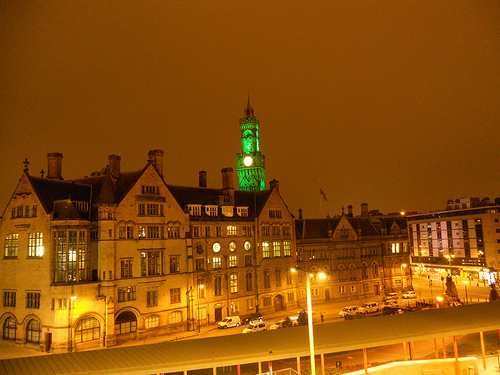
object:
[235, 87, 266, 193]
clock tower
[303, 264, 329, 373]
street light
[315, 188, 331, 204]
flag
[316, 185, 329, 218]
pole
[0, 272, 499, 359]
street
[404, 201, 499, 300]
building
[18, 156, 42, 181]
sculptures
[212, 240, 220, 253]
lights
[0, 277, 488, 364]
walkway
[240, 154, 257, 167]
clock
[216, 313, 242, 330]
van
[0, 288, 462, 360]
roadway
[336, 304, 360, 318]
vehicles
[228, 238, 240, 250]
windows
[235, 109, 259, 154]
steeple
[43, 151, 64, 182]
chimneys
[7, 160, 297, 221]
roof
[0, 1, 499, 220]
sky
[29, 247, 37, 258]
window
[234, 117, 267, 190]
light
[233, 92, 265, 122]
top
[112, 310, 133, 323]
window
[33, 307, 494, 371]
panel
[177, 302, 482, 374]
bridge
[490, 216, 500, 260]
ladder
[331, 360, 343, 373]
trash can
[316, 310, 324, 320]
man